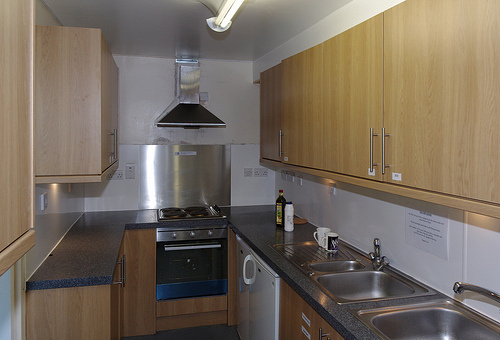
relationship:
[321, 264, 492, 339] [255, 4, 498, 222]
sink near cabinets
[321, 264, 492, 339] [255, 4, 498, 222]
sink below cabinets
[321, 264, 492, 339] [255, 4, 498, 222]
sink under cabinets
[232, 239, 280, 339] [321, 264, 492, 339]
dishwasher near sink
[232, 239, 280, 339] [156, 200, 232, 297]
dishwasher near stove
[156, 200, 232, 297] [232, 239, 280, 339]
stove near dishwasher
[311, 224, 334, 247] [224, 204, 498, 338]
mug on counter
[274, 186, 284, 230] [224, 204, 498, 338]
bottle on counter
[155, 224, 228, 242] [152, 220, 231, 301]
control panel for oven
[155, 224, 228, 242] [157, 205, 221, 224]
control panel for stove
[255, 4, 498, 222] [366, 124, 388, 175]
cabinets with handle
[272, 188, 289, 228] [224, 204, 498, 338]
bottle on counter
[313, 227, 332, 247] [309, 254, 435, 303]
mug beside sink